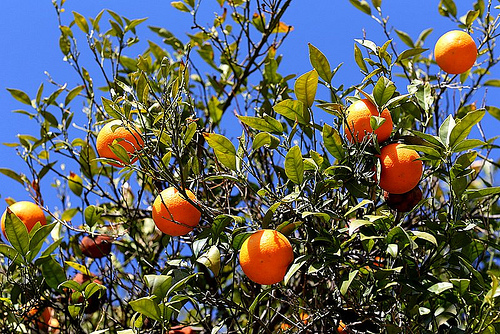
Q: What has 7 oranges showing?
A: The orange grove tree.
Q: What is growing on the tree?
A: Orange.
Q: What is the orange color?
A: Orange.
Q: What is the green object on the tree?
A: Leaves.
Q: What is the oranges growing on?
A: Tree.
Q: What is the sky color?
A: Blue.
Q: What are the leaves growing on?
A: Tree.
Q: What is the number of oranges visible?
A: Seven.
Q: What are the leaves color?
A: Green.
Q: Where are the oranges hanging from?
A: Branch.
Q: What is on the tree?
A: Oranges and leaves.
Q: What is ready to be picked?
A: The oranges.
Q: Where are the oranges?
A: In a tree.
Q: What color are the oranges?
A: Orange.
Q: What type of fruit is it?
A: Oranges.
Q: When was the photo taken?
A: Daytime.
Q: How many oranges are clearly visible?
A: Seven.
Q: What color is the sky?
A: Blue.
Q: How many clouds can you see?
A: None.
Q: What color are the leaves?
A: Green.